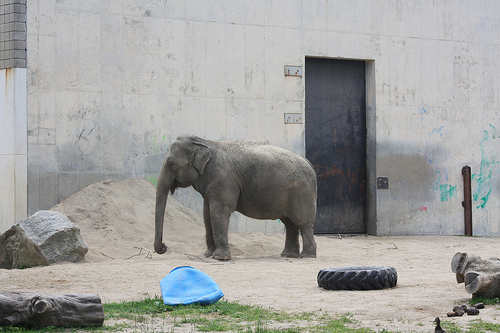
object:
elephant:
[153, 135, 320, 261]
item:
[159, 265, 226, 308]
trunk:
[154, 167, 174, 255]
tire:
[317, 264, 400, 289]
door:
[304, 56, 368, 233]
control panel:
[377, 176, 389, 190]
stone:
[0, 209, 90, 269]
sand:
[0, 241, 499, 333]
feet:
[279, 247, 322, 257]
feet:
[203, 245, 233, 263]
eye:
[168, 159, 176, 169]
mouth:
[171, 178, 184, 192]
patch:
[0, 294, 369, 333]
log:
[0, 291, 104, 328]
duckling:
[432, 316, 445, 333]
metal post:
[460, 166, 474, 236]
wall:
[0, 0, 499, 237]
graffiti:
[436, 124, 495, 208]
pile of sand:
[50, 174, 206, 253]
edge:
[326, 271, 377, 282]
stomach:
[237, 184, 283, 220]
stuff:
[414, 105, 452, 169]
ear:
[191, 142, 217, 173]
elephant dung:
[466, 307, 481, 314]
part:
[209, 195, 233, 260]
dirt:
[246, 263, 310, 304]